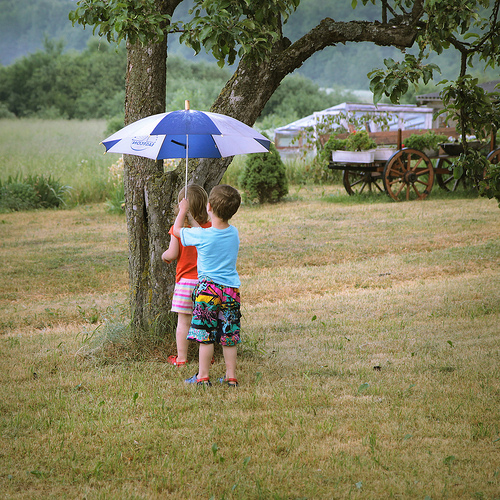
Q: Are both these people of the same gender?
A: No, they are both male and female.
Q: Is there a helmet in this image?
A: No, there are no helmets.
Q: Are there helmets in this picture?
A: No, there are no helmets.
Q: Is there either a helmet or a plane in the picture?
A: No, there are no helmets or airplanes.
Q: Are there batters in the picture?
A: No, there are no batters.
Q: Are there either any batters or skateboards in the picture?
A: No, there are no batters or skateboards.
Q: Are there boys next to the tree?
A: Yes, there is a boy next to the tree.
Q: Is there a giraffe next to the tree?
A: No, there is a boy next to the tree.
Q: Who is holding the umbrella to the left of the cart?
A: The boy is holding the umbrella.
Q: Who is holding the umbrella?
A: The boy is holding the umbrella.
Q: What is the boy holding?
A: The boy is holding the umbrella.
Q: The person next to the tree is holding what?
A: The boy is holding the umbrella.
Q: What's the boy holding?
A: The boy is holding the umbrella.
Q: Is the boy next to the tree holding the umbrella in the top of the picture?
A: Yes, the boy is holding the umbrella.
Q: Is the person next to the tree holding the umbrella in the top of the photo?
A: Yes, the boy is holding the umbrella.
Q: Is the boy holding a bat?
A: No, the boy is holding the umbrella.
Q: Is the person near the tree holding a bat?
A: No, the boy is holding the umbrella.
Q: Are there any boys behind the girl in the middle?
A: Yes, there is a boy behind the girl.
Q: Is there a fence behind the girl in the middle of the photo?
A: No, there is a boy behind the girl.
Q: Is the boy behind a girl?
A: Yes, the boy is behind a girl.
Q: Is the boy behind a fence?
A: No, the boy is behind a girl.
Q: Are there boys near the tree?
A: Yes, there is a boy near the tree.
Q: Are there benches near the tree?
A: No, there is a boy near the tree.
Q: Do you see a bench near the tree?
A: No, there is a boy near the tree.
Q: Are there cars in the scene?
A: No, there are no cars.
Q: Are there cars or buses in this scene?
A: No, there are no cars or buses.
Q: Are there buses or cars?
A: No, there are no cars or buses.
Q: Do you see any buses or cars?
A: No, there are no cars or buses.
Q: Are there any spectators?
A: No, there are no spectators.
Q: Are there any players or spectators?
A: No, there are no spectators or players.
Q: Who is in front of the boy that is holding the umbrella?
A: The girl is in front of the boy.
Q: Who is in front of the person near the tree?
A: The girl is in front of the boy.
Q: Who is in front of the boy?
A: The girl is in front of the boy.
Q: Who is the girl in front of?
A: The girl is in front of the boy.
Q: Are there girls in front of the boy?
A: Yes, there is a girl in front of the boy.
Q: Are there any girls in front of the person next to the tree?
A: Yes, there is a girl in front of the boy.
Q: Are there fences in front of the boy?
A: No, there is a girl in front of the boy.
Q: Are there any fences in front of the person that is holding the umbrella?
A: No, there is a girl in front of the boy.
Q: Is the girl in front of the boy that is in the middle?
A: Yes, the girl is in front of the boy.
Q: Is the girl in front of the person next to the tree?
A: Yes, the girl is in front of the boy.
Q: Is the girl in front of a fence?
A: No, the girl is in front of the boy.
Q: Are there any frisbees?
A: No, there are no frisbees.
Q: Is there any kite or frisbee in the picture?
A: No, there are no frisbees or kites.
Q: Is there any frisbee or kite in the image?
A: No, there are no frisbees or kites.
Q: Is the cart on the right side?
A: Yes, the cart is on the right of the image.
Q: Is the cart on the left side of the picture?
A: No, the cart is on the right of the image.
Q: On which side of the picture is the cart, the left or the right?
A: The cart is on the right of the image.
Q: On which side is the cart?
A: The cart is on the right of the image.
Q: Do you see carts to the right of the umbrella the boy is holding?
A: Yes, there is a cart to the right of the umbrella.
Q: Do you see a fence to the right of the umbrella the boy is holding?
A: No, there is a cart to the right of the umbrella.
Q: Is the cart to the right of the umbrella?
A: Yes, the cart is to the right of the umbrella.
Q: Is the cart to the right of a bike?
A: No, the cart is to the right of the umbrella.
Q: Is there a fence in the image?
A: No, there are no fences.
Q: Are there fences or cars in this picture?
A: No, there are no fences or cars.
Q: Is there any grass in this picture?
A: Yes, there is grass.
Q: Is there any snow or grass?
A: Yes, there is grass.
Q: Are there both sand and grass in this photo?
A: No, there is grass but no sand.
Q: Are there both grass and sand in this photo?
A: No, there is grass but no sand.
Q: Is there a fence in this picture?
A: No, there are no fences.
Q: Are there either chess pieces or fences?
A: No, there are no fences or chess pieces.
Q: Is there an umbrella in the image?
A: Yes, there is an umbrella.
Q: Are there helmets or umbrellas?
A: Yes, there is an umbrella.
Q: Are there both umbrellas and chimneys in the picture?
A: No, there is an umbrella but no chimneys.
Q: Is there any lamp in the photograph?
A: No, there are no lamps.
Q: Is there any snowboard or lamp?
A: No, there are no lamps or snowboards.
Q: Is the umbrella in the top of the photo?
A: Yes, the umbrella is in the top of the image.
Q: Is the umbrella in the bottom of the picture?
A: No, the umbrella is in the top of the image.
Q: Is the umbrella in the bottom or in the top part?
A: The umbrella is in the top of the image.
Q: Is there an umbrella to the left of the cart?
A: Yes, there is an umbrella to the left of the cart.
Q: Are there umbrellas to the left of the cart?
A: Yes, there is an umbrella to the left of the cart.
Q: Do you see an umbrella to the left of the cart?
A: Yes, there is an umbrella to the left of the cart.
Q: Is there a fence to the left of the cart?
A: No, there is an umbrella to the left of the cart.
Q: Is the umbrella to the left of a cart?
A: Yes, the umbrella is to the left of a cart.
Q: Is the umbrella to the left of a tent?
A: No, the umbrella is to the left of a cart.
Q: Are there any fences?
A: No, there are no fences.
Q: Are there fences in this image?
A: No, there are no fences.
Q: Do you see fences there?
A: No, there are no fences.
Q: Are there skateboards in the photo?
A: No, there are no skateboards.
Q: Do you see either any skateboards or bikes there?
A: No, there are no skateboards or bikes.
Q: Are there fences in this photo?
A: No, there are no fences.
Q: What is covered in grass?
A: The ground is covered in grass.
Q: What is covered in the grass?
A: The ground is covered in grass.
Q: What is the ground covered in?
A: The ground is covered in grass.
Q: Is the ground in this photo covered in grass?
A: Yes, the ground is covered in grass.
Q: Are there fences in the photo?
A: No, there are no fences.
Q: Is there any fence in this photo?
A: No, there are no fences.